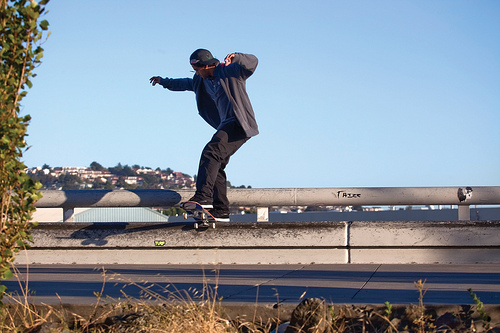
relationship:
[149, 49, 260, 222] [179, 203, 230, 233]
he grinding on h skateboard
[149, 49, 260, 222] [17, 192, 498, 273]
he doing a trick on railing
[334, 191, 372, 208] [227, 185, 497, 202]
graffiti on railing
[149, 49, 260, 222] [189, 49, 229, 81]
he wearing a cap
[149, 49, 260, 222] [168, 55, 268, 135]
he wearing a jacket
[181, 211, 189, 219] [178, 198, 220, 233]
wheel mounted on skateboard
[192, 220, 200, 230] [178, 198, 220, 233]
wheel mounted on skateboard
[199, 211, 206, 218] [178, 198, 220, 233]
wheel mounted on skateboard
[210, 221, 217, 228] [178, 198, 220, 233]
wheel mounted on skateboard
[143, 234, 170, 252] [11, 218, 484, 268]
sticker stuck on wall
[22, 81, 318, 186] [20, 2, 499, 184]
cloud hanging in blue sky